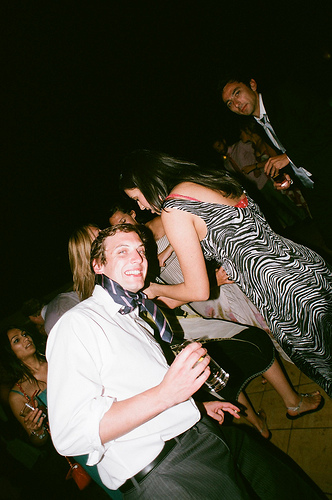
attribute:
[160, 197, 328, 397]
dress — black, white, zebra striped, cocktail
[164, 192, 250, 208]
undergarment — red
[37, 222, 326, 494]
boy — posing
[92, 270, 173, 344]
tie — blue, gold, striped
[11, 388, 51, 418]
dress — green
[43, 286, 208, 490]
shirt — white, dressy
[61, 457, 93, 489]
handbag — dark red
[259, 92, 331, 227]
suit — dark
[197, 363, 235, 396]
glass — empty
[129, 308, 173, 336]
tie — black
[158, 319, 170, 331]
stripes — pink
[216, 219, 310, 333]
dress — heinous, black and white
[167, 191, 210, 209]
bra — pink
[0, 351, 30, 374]
hair — long, black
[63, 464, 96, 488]
purse — brown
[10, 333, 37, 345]
expression — confused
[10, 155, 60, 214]
darkness — black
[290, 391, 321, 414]
sandal — silver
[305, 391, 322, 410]
foot — dirty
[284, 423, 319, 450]
tile — brownish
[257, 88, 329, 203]
suit — black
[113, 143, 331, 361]
girl — white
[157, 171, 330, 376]
dress — black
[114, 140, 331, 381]
woman — white, black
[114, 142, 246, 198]
hair — long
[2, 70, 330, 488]
people — dancing 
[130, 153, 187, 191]
hair — long , dark 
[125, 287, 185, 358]
tie — blue 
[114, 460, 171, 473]
belt — black , leather 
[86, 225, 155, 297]
guy — smiling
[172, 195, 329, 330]
dress — black , white